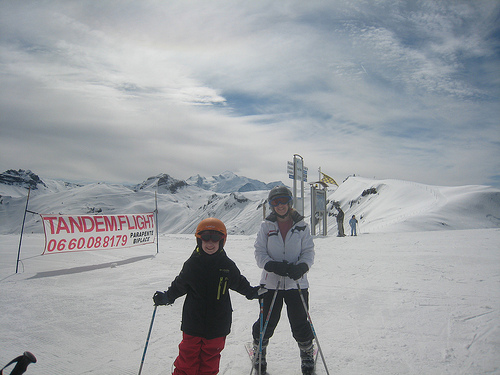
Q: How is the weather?
A: It is cloudy.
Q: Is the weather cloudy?
A: Yes, it is cloudy.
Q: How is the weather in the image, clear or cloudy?
A: It is cloudy.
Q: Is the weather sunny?
A: No, it is cloudy.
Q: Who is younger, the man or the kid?
A: The kid is younger than the man.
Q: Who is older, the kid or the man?
A: The man is older than the kid.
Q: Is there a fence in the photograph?
A: No, there are no fences.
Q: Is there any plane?
A: No, there are no airplanes.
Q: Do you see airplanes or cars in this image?
A: No, there are no airplanes or cars.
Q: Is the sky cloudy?
A: Yes, the sky is cloudy.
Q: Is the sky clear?
A: No, the sky is cloudy.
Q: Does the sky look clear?
A: No, the sky is cloudy.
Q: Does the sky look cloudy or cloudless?
A: The sky is cloudy.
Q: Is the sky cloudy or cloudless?
A: The sky is cloudy.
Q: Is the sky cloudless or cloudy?
A: The sky is cloudy.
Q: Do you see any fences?
A: No, there are no fences.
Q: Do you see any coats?
A: Yes, there is a coat.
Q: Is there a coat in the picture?
A: Yes, there is a coat.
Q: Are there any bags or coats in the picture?
A: Yes, there is a coat.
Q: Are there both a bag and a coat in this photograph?
A: No, there is a coat but no bags.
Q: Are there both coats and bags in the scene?
A: No, there is a coat but no bags.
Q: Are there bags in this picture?
A: No, there are no bags.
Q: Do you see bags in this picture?
A: No, there are no bags.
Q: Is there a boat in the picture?
A: No, there are no boats.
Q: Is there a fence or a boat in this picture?
A: No, there are no boats or fences.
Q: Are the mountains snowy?
A: Yes, the mountains are snowy.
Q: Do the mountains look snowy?
A: Yes, the mountains are snowy.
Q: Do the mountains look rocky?
A: No, the mountains are snowy.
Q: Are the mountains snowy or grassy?
A: The mountains are snowy.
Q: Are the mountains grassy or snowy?
A: The mountains are snowy.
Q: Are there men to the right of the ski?
A: Yes, there is a man to the right of the ski.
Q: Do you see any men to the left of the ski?
A: No, the man is to the right of the ski.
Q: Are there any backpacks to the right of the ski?
A: No, there is a man to the right of the ski.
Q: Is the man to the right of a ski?
A: Yes, the man is to the right of a ski.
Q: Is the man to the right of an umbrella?
A: No, the man is to the right of a ski.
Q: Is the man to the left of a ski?
A: No, the man is to the right of a ski.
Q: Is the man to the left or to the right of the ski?
A: The man is to the right of the ski.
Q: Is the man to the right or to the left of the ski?
A: The man is to the right of the ski.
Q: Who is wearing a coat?
A: The man is wearing a coat.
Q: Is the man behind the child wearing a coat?
A: Yes, the man is wearing a coat.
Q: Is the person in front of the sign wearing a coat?
A: Yes, the man is wearing a coat.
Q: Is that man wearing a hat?
A: No, the man is wearing a coat.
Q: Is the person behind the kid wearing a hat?
A: No, the man is wearing a coat.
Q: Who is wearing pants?
A: The man is wearing pants.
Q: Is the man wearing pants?
A: Yes, the man is wearing pants.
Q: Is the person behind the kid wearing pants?
A: Yes, the man is wearing pants.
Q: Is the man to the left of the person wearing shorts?
A: No, the man is wearing pants.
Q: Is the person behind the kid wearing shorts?
A: No, the man is wearing pants.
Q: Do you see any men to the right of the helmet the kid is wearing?
A: Yes, there is a man to the right of the helmet.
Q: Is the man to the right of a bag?
A: No, the man is to the right of the helmet.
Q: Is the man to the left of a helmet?
A: No, the man is to the right of a helmet.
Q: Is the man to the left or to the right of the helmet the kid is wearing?
A: The man is to the right of the helmet.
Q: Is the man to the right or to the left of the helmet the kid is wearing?
A: The man is to the right of the helmet.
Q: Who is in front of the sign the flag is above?
A: The man is in front of the sign.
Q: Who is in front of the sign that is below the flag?
A: The man is in front of the sign.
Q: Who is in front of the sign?
A: The man is in front of the sign.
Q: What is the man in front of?
A: The man is in front of the sign.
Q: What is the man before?
A: The man is in front of the sign.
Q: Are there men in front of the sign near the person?
A: Yes, there is a man in front of the sign.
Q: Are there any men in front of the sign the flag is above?
A: Yes, there is a man in front of the sign.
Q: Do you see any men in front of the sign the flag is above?
A: Yes, there is a man in front of the sign.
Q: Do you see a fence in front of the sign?
A: No, there is a man in front of the sign.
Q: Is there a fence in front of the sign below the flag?
A: No, there is a man in front of the sign.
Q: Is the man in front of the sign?
A: Yes, the man is in front of the sign.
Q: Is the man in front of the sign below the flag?
A: Yes, the man is in front of the sign.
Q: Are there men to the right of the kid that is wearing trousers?
A: Yes, there is a man to the right of the child.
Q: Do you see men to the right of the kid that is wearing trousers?
A: Yes, there is a man to the right of the child.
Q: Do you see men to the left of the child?
A: No, the man is to the right of the child.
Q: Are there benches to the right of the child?
A: No, there is a man to the right of the child.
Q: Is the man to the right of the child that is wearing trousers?
A: Yes, the man is to the right of the child.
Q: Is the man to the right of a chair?
A: No, the man is to the right of the child.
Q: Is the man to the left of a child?
A: No, the man is to the right of a child.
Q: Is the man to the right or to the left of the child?
A: The man is to the right of the child.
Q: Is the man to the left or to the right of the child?
A: The man is to the right of the child.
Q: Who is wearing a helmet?
A: The man is wearing a helmet.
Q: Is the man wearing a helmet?
A: Yes, the man is wearing a helmet.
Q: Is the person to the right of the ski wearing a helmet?
A: Yes, the man is wearing a helmet.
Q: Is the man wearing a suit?
A: No, the man is wearing a helmet.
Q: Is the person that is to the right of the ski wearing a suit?
A: No, the man is wearing a helmet.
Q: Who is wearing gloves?
A: The man is wearing gloves.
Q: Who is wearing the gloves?
A: The man is wearing gloves.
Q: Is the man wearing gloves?
A: Yes, the man is wearing gloves.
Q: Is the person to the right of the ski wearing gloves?
A: Yes, the man is wearing gloves.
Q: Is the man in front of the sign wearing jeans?
A: No, the man is wearing gloves.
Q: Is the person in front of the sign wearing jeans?
A: No, the man is wearing gloves.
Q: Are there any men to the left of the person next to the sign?
A: Yes, there is a man to the left of the person.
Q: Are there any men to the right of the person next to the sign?
A: No, the man is to the left of the person.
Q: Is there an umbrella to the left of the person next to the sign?
A: No, there is a man to the left of the person.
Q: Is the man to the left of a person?
A: Yes, the man is to the left of a person.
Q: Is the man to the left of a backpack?
A: No, the man is to the left of a person.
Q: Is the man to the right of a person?
A: No, the man is to the left of a person.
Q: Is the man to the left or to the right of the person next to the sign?
A: The man is to the left of the person.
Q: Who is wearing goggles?
A: The man is wearing goggles.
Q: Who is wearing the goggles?
A: The man is wearing goggles.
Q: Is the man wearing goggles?
A: Yes, the man is wearing goggles.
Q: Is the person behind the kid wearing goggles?
A: Yes, the man is wearing goggles.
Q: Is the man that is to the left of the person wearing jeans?
A: No, the man is wearing goggles.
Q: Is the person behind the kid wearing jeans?
A: No, the man is wearing goggles.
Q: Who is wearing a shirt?
A: The man is wearing a shirt.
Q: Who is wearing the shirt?
A: The man is wearing a shirt.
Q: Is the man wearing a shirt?
A: Yes, the man is wearing a shirt.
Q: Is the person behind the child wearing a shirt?
A: Yes, the man is wearing a shirt.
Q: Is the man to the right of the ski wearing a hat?
A: No, the man is wearing a shirt.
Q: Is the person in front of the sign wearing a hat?
A: No, the man is wearing a shirt.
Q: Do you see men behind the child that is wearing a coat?
A: Yes, there is a man behind the kid.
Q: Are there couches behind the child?
A: No, there is a man behind the child.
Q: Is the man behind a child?
A: Yes, the man is behind a child.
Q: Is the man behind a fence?
A: No, the man is behind a child.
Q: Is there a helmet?
A: Yes, there is a helmet.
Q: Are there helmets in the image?
A: Yes, there is a helmet.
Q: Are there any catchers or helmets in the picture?
A: Yes, there is a helmet.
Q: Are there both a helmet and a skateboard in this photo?
A: No, there is a helmet but no skateboards.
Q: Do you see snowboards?
A: No, there are no snowboards.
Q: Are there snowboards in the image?
A: No, there are no snowboards.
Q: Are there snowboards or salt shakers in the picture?
A: No, there are no snowboards or salt shakers.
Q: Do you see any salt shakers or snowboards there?
A: No, there are no snowboards or salt shakers.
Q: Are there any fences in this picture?
A: No, there are no fences.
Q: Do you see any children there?
A: Yes, there is a child.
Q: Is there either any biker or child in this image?
A: Yes, there is a child.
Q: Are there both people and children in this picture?
A: Yes, there are both a child and a person.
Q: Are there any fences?
A: No, there are no fences.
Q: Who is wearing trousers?
A: The child is wearing trousers.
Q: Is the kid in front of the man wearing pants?
A: Yes, the kid is wearing pants.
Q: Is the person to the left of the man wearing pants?
A: Yes, the kid is wearing pants.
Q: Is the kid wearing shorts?
A: No, the kid is wearing pants.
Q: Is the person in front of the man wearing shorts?
A: No, the kid is wearing pants.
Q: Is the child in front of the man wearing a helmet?
A: Yes, the kid is wearing a helmet.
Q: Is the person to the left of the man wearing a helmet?
A: Yes, the kid is wearing a helmet.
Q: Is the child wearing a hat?
A: No, the child is wearing a helmet.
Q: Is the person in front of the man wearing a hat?
A: No, the child is wearing a helmet.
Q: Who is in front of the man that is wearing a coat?
A: The child is in front of the man.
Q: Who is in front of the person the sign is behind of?
A: The child is in front of the man.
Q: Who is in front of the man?
A: The child is in front of the man.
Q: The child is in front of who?
A: The child is in front of the man.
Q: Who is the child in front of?
A: The child is in front of the man.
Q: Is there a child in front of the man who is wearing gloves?
A: Yes, there is a child in front of the man.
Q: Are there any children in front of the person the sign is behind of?
A: Yes, there is a child in front of the man.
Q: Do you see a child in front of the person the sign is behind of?
A: Yes, there is a child in front of the man.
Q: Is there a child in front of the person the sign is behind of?
A: Yes, there is a child in front of the man.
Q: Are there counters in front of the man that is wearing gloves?
A: No, there is a child in front of the man.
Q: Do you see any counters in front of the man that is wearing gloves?
A: No, there is a child in front of the man.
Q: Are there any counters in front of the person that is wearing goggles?
A: No, there is a child in front of the man.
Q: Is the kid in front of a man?
A: Yes, the kid is in front of a man.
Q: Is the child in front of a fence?
A: No, the child is in front of a man.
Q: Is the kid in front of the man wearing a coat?
A: Yes, the child is wearing a coat.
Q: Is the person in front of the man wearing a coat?
A: Yes, the child is wearing a coat.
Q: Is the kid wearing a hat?
A: No, the kid is wearing a coat.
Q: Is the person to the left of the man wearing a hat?
A: No, the kid is wearing a coat.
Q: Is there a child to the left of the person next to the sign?
A: Yes, there is a child to the left of the person.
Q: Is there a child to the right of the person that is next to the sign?
A: No, the child is to the left of the person.